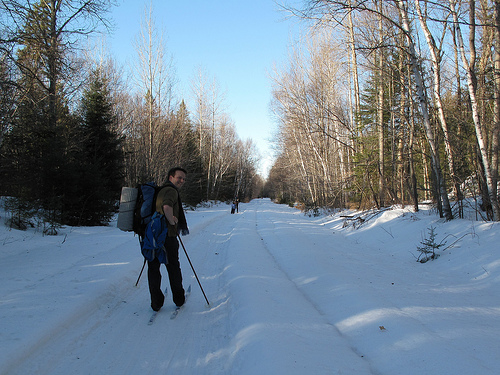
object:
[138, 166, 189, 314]
person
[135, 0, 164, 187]
tree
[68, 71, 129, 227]
evergreen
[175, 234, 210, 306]
pole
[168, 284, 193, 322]
ski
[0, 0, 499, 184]
sky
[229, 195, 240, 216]
man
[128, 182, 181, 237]
backpack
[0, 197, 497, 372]
ground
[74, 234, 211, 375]
trail